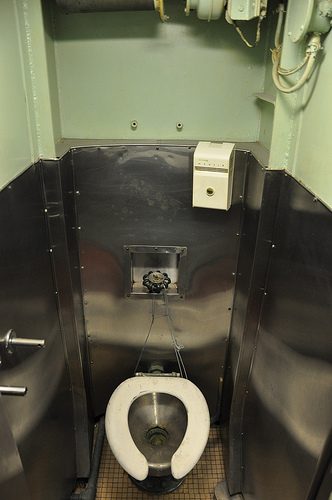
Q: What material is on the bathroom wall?
A: Metal.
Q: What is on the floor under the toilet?
A: Tiles.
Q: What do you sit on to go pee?
A: Toilet seat.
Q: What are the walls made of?
A: Metal.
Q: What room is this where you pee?
A: Bathroom.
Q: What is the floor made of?
A: Small tiles.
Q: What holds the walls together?
A: Bolts.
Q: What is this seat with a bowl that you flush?
A: A toilet.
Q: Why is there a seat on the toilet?
A: To sit down.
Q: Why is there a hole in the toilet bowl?
A: So water goes down.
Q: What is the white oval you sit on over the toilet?
A: Toilet seat.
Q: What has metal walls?
A: The bathroom stall.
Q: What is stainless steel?
A: The toilet bowl.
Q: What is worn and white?
A: The toilet seat.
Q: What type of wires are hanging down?
A: Electrical.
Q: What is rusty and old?
A: The toilet bowl.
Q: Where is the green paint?
A: On the upper walls.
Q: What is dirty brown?
A: The tile floor.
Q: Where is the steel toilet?
A: In the bathroom.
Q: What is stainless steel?
A: The toilet bowl.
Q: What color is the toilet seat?
A: White.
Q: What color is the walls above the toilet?
A: Green.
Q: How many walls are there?
A: Three.